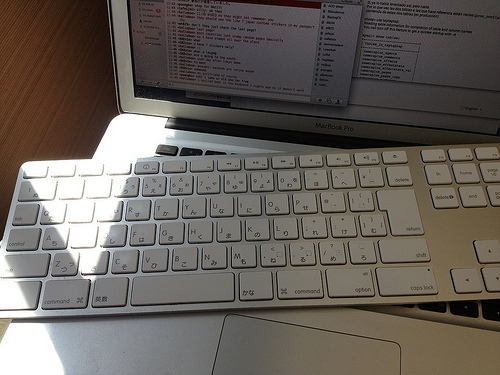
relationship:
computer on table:
[0, 0, 500, 375] [70, 92, 487, 373]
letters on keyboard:
[145, 189, 332, 250] [36, 143, 488, 297]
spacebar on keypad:
[130, 266, 238, 306] [0, 140, 495, 322]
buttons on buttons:
[92, 123, 233, 193] [0, 146, 500, 310]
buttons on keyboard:
[450, 230, 498, 298] [82, 151, 498, 368]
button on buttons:
[372, 186, 427, 236] [0, 146, 500, 310]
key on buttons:
[152, 196, 181, 226] [0, 146, 500, 310]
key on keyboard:
[105, 248, 137, 276] [37, 143, 432, 314]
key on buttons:
[95, 199, 123, 222] [0, 146, 500, 310]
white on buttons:
[127, 199, 155, 217] [0, 146, 500, 310]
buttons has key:
[0, 146, 500, 310] [244, 218, 271, 242]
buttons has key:
[0, 146, 500, 310] [52, 182, 94, 226]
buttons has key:
[0, 146, 500, 310] [63, 190, 102, 227]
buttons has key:
[0, 146, 500, 310] [109, 246, 137, 275]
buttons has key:
[0, 146, 500, 310] [258, 241, 285, 265]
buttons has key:
[0, 146, 500, 310] [123, 200, 148, 220]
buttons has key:
[0, 146, 500, 310] [347, 238, 374, 263]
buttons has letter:
[0, 146, 500, 310] [228, 240, 256, 270]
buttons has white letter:
[0, 146, 500, 310] [188, 219, 214, 242]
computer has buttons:
[56, 1, 498, 356] [0, 146, 500, 310]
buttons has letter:
[0, 146, 500, 310] [213, 219, 245, 244]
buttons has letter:
[0, 146, 500, 310] [172, 245, 195, 267]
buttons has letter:
[0, 146, 500, 310] [210, 195, 232, 215]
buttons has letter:
[0, 146, 500, 310] [277, 169, 302, 190]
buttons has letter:
[0, 146, 500, 310] [127, 199, 153, 219]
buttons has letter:
[0, 146, 500, 310] [111, 252, 123, 267]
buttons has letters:
[0, 146, 500, 310] [42, 187, 386, 277]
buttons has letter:
[0, 146, 500, 310] [137, 197, 196, 227]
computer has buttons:
[0, 0, 500, 375] [0, 146, 500, 310]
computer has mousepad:
[0, 0, 500, 375] [212, 313, 401, 375]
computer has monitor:
[0, 0, 500, 375] [130, 2, 497, 119]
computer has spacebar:
[0, 0, 500, 375] [128, 272, 250, 319]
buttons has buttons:
[0, 146, 500, 310] [419, 304, 497, 321]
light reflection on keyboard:
[38, 101, 169, 264] [10, 161, 499, 313]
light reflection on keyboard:
[38, 101, 169, 264] [9, 113, 499, 373]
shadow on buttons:
[5, 150, 498, 357] [13, 151, 490, 295]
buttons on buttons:
[13, 151, 490, 295] [0, 146, 500, 310]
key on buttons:
[205, 196, 238, 218] [0, 146, 500, 310]